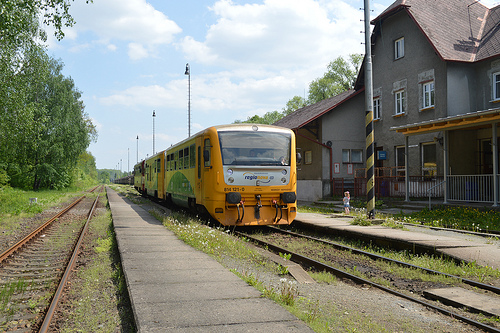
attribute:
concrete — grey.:
[91, 171, 288, 331]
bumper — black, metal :
[225, 190, 242, 206]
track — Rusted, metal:
[238, 223, 498, 329]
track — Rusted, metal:
[1, 177, 103, 332]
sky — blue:
[89, 52, 132, 80]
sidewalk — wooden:
[103, 182, 315, 331]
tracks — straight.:
[0, 176, 107, 331]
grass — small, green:
[87, 203, 115, 237]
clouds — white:
[186, 6, 349, 71]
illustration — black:
[164, 170, 196, 200]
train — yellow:
[112, 118, 297, 228]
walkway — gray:
[101, 182, 312, 330]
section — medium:
[115, 230, 205, 257]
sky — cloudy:
[27, 6, 372, 169]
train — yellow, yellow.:
[131, 122, 296, 225]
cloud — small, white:
[7, 2, 499, 174]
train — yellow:
[151, 107, 326, 229]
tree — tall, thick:
[0, 41, 96, 195]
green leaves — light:
[14, 83, 70, 168]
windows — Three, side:
[367, 72, 442, 124]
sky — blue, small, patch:
[8, 0, 394, 172]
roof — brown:
[271, 86, 353, 127]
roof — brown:
[381, 0, 498, 60]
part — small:
[466, 4, 494, 48]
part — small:
[373, 2, 420, 18]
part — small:
[346, 76, 367, 101]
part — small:
[294, 119, 326, 139]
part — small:
[394, 117, 475, 128]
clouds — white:
[233, 5, 330, 74]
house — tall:
[329, 10, 494, 202]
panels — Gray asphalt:
[104, 185, 311, 331]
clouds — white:
[90, 5, 180, 50]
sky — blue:
[62, 9, 316, 112]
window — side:
[202, 139, 215, 169]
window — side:
[196, 143, 201, 178]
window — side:
[186, 144, 197, 167]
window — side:
[175, 145, 191, 172]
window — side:
[151, 157, 165, 177]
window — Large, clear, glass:
[213, 126, 292, 166]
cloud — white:
[13, 0, 180, 72]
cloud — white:
[126, 42, 146, 62]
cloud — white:
[101, 73, 361, 113]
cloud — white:
[207, 0, 373, 73]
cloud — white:
[138, 120, 207, 159]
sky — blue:
[2, 0, 497, 172]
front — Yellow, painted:
[213, 126, 302, 227]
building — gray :
[317, 4, 478, 235]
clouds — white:
[164, 8, 362, 88]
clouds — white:
[139, 0, 371, 130]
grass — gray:
[160, 184, 288, 281]